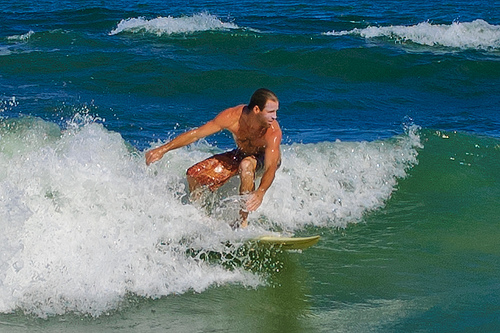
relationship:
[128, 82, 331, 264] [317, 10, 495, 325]
surfing in ocean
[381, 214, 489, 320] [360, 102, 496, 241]
green ocean water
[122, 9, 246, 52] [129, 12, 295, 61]
small wave crashing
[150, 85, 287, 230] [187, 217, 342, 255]
man riding surfboard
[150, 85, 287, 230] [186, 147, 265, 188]
man wearing shorts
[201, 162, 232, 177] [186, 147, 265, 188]
orange board shorts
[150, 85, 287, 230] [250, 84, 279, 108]
man has hair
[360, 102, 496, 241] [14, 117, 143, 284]
water and waves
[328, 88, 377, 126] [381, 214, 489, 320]
blue and green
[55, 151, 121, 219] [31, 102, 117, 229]
white water splash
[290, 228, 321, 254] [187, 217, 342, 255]
nose of surfboard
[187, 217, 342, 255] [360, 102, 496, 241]
surfboard in water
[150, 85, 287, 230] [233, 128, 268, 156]
man with hair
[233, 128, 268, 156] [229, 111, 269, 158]
hair on chest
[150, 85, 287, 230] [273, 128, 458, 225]
man rides wave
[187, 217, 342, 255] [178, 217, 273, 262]
surfboard partially hidden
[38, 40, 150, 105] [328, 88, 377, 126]
water deep blue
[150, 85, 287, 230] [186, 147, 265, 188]
man wears shorts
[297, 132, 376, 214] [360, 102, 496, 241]
churned up water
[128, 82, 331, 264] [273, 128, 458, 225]
surfer on wave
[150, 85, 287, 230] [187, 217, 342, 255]
surfer on surfboard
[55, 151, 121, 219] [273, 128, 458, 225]
white water wave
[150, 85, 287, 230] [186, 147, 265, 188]
swimmer in shorts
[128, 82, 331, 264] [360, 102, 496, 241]
surfer on water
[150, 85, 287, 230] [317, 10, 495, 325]
surfer in ocean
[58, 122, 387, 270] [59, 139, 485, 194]
riding ocean waves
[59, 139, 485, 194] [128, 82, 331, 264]
waves for surfing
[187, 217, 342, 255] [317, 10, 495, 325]
surfboard in ocean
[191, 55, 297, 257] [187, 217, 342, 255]
standing on surfboard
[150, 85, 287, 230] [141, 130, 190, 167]
surfer has hand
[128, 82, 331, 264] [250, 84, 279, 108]
surfer has hair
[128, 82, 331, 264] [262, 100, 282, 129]
surfer has face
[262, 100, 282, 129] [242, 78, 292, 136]
face to right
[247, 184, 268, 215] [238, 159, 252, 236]
hand touching leg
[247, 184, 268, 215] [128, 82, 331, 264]
hand of surfer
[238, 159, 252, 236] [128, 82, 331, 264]
leg of surfer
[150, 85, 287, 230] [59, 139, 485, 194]
person surfing waves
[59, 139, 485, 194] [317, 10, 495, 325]
waves in ocean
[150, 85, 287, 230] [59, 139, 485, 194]
man surfing waves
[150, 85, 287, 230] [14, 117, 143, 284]
man surfing waves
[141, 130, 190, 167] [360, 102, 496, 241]
hand in water